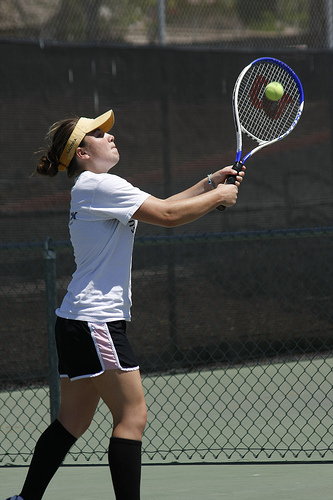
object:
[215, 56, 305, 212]
racket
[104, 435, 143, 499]
sock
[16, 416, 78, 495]
sock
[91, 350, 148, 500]
leg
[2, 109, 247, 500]
lady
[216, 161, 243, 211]
handle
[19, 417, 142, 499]
socks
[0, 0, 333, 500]
ground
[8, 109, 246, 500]
player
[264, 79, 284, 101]
ball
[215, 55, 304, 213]
racquet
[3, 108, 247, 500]
woman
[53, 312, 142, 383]
shorts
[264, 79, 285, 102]
yellow ball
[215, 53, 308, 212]
tennis bat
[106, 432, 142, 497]
black socks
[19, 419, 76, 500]
black socks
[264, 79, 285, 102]
tennis ball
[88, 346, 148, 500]
leg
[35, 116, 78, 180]
hair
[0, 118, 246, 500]
woman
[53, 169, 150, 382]
dress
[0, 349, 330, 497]
ground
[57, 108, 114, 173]
visor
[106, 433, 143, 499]
socks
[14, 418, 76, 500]
socks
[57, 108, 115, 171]
cap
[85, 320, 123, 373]
strip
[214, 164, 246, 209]
hands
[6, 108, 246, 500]
lady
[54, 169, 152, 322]
shirt